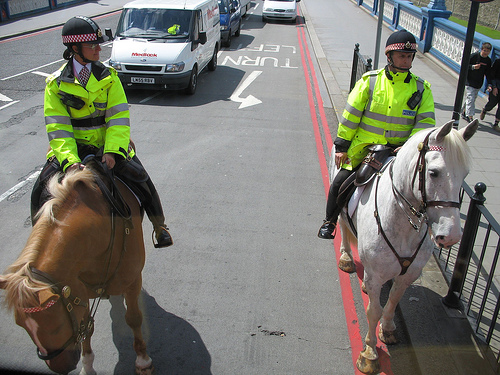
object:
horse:
[0, 162, 150, 374]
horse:
[332, 122, 478, 375]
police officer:
[30, 17, 173, 250]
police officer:
[319, 28, 434, 238]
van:
[105, 1, 223, 95]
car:
[261, 0, 299, 22]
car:
[218, 0, 243, 47]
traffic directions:
[215, 43, 298, 111]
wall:
[357, 2, 500, 93]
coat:
[42, 59, 136, 172]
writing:
[130, 52, 158, 59]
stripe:
[290, 0, 370, 375]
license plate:
[131, 77, 156, 84]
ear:
[430, 119, 456, 142]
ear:
[459, 118, 480, 142]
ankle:
[134, 354, 153, 368]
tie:
[78, 66, 90, 85]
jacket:
[334, 67, 434, 171]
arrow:
[229, 69, 263, 111]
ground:
[1, 0, 500, 373]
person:
[461, 42, 492, 122]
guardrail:
[432, 171, 499, 374]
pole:
[452, 1, 481, 129]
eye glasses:
[83, 42, 99, 49]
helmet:
[60, 14, 111, 46]